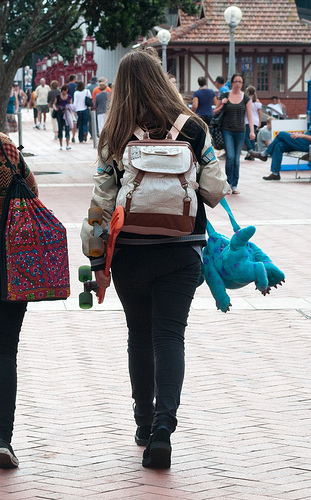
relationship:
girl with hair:
[80, 45, 230, 470] [98, 49, 210, 165]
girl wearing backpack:
[80, 45, 230, 470] [113, 112, 201, 238]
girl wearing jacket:
[80, 45, 230, 470] [81, 110, 233, 268]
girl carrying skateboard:
[80, 45, 230, 470] [78, 204, 125, 309]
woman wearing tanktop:
[211, 71, 255, 196] [219, 91, 251, 129]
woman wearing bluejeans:
[211, 71, 255, 196] [219, 132, 246, 185]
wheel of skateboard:
[78, 290, 93, 311] [78, 204, 125, 309]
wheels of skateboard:
[80, 264, 93, 308] [78, 204, 125, 309]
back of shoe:
[154, 433, 168, 447] [142, 427, 173, 470]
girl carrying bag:
[80, 45, 230, 470] [202, 198, 286, 313]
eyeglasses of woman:
[233, 80, 243, 85] [211, 71, 255, 196]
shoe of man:
[32, 124, 43, 136] [32, 78, 52, 131]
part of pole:
[228, 32, 235, 46] [229, 23, 240, 79]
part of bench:
[294, 156, 302, 170] [282, 148, 309, 180]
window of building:
[257, 52, 270, 92] [131, 1, 309, 117]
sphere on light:
[157, 28, 171, 42] [223, 4, 243, 24]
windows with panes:
[221, 54, 288, 94] [257, 70, 267, 82]